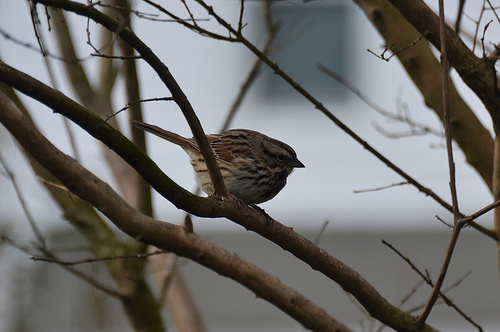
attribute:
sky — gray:
[6, 8, 491, 330]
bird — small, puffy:
[132, 122, 304, 199]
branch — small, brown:
[329, 0, 499, 193]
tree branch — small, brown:
[2, 27, 196, 330]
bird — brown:
[132, 109, 318, 217]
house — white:
[484, 2, 491, 232]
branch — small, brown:
[0, 87, 354, 330]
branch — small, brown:
[0, 58, 440, 330]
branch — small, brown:
[34, 0, 226, 196]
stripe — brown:
[217, 133, 257, 174]